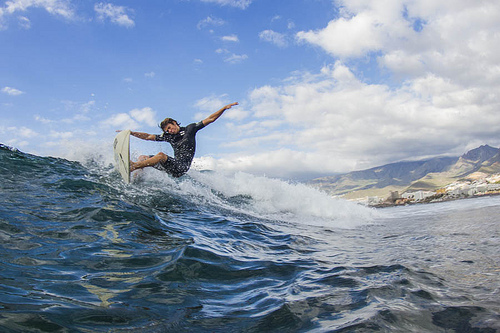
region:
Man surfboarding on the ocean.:
[102, 98, 247, 188]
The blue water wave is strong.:
[11, 141, 466, 286]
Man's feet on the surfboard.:
[110, 95, 140, 190]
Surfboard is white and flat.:
[110, 125, 137, 191]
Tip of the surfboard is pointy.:
[111, 125, 141, 140]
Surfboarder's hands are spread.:
[105, 95, 250, 140]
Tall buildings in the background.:
[345, 172, 496, 207]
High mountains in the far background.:
[310, 140, 495, 175]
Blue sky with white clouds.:
[5, 5, 495, 130]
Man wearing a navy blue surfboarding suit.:
[145, 117, 205, 177]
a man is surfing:
[112, 102, 238, 184]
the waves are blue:
[2, 145, 498, 329]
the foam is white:
[190, 171, 382, 220]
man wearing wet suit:
[150, 119, 202, 177]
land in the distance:
[301, 143, 498, 206]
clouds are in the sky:
[0, 0, 498, 180]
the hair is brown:
[157, 119, 182, 129]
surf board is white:
[112, 128, 132, 181]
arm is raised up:
[197, 102, 237, 129]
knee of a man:
[157, 151, 164, 158]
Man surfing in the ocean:
[109, 100, 239, 186]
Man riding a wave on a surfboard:
[109, 98, 239, 191]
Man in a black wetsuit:
[112, 100, 239, 179]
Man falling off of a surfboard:
[115, 99, 240, 193]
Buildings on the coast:
[369, 178, 499, 210]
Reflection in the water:
[80, 174, 135, 316]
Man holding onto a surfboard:
[109, 100, 240, 195]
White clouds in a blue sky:
[0, 0, 498, 169]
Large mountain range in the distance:
[307, 143, 498, 197]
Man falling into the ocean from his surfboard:
[114, 97, 241, 188]